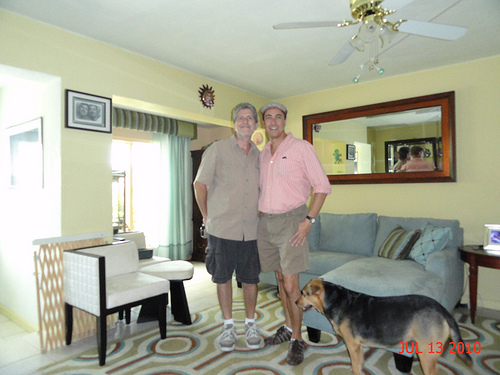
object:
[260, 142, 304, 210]
pink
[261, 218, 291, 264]
beige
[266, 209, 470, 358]
couch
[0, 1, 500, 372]
living room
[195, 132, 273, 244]
shirt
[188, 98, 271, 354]
guys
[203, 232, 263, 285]
black shorts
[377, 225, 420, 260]
pillows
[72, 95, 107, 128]
picture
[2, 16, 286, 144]
wall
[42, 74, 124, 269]
wall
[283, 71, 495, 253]
wall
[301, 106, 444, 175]
mirror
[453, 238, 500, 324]
table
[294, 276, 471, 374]
dog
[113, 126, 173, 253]
window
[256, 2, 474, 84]
ceiling fan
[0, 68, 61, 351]
gate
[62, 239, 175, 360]
chair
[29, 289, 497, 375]
carpet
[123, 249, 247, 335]
floor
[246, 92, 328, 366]
man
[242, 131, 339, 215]
shirt